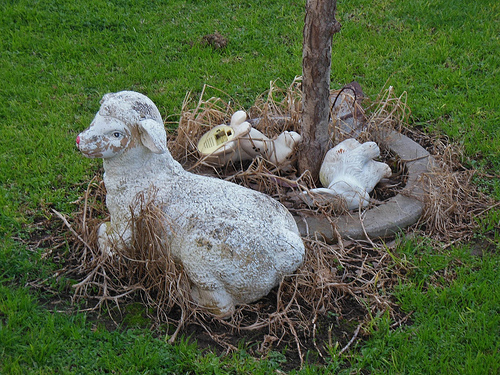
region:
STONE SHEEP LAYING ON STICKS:
[63, 61, 315, 308]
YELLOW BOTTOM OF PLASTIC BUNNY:
[181, 111, 272, 156]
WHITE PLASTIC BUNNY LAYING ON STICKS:
[201, 101, 294, 164]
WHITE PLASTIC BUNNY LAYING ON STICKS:
[320, 131, 394, 211]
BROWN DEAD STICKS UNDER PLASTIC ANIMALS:
[66, 50, 469, 332]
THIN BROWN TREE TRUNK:
[285, 7, 331, 174]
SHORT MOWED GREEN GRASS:
[23, 10, 498, 117]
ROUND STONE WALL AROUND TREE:
[281, 84, 458, 253]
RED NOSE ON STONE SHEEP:
[65, 131, 81, 149]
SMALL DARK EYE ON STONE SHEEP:
[108, 131, 126, 142]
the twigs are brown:
[301, 232, 393, 329]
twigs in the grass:
[302, 210, 469, 360]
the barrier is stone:
[292, 187, 440, 273]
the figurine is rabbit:
[317, 135, 393, 211]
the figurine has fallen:
[291, 134, 388, 215]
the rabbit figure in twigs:
[280, 147, 382, 212]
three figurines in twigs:
[94, 81, 390, 299]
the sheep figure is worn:
[92, 97, 320, 280]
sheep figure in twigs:
[72, 94, 294, 336]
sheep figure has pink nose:
[69, 90, 169, 159]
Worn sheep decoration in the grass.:
[72, 88, 307, 318]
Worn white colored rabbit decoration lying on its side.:
[300, 136, 394, 205]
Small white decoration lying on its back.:
[196, 107, 301, 166]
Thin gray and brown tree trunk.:
[297, 0, 347, 178]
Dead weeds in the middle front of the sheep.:
[130, 197, 194, 338]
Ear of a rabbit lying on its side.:
[297, 189, 347, 211]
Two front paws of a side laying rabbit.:
[362, 142, 395, 180]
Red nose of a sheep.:
[72, 131, 80, 144]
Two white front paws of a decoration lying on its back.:
[227, 107, 270, 150]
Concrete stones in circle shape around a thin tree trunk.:
[197, 110, 446, 241]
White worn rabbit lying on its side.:
[293, 137, 393, 212]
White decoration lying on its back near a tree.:
[188, 107, 303, 169]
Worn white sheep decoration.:
[67, 90, 308, 318]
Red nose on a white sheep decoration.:
[73, 135, 84, 144]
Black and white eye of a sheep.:
[112, 129, 120, 143]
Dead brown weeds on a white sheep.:
[116, 192, 206, 330]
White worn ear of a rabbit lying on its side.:
[297, 185, 344, 215]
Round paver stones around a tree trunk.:
[190, 110, 442, 241]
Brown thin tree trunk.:
[297, 0, 343, 177]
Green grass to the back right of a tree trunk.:
[346, 7, 481, 95]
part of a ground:
[317, 306, 349, 332]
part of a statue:
[252, 239, 292, 299]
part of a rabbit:
[341, 142, 375, 202]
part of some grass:
[440, 272, 472, 292]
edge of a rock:
[371, 202, 398, 222]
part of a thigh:
[186, 222, 234, 269]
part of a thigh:
[152, 134, 201, 194]